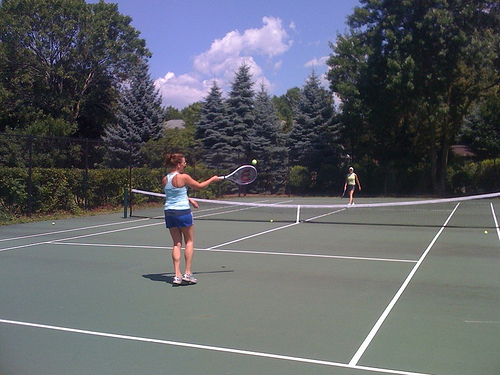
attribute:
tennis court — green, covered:
[1, 197, 498, 372]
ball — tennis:
[250, 158, 257, 165]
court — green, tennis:
[35, 76, 498, 361]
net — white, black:
[125, 185, 497, 229]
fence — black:
[126, 181, 498, 226]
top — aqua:
[160, 169, 190, 211]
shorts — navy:
[160, 208, 196, 229]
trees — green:
[29, 52, 79, 122]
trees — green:
[106, 73, 163, 167]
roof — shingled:
[174, 120, 187, 128]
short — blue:
[165, 211, 190, 229]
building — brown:
[449, 139, 486, 162]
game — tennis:
[3, 148, 493, 373]